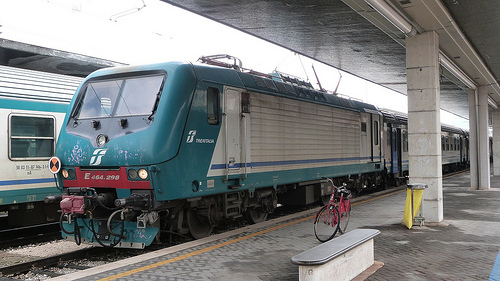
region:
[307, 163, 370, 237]
The bicycle is red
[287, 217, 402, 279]
The bench is in front of the bicycle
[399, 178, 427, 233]
The trash bag is yellow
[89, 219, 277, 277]
The line is yellow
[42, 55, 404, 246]
The train is green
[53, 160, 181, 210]
The sign on the front of the train is red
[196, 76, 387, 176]
The side of the train is white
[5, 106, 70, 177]
The window is closed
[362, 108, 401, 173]
The door of the train is closed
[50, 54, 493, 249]
An aqua and white train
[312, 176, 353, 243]
A red bike parked near train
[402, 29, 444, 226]
A concrete pillar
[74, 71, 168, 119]
A windsheild of a train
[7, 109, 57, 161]
A window on side of train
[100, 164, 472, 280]
A yellow line on ground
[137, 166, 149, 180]
A round headlight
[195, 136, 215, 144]
Words on the side of train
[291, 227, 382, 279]
A bench on platform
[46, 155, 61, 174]
An orange and black sign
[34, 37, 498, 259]
train on the tracks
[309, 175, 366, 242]
red and black bike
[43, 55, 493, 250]
train in the station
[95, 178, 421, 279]
yellow line painted on the ground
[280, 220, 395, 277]
small concrete bench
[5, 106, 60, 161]
window on the side of the train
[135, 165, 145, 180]
light on the front of the train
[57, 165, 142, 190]
red paint on the front of the train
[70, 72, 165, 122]
windows on the front of the train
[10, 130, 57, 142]
metal bar on the window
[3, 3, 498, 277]
scene outside at a train station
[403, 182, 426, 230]
yellow trash receptacle on the platform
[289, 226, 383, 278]
solid cement gray and light tan bench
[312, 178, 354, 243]
red bicycle parked on the platform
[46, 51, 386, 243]
blue and gray train engine with red trim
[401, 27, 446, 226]
light gray cement block support column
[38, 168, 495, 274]
gray cobblestone on the platform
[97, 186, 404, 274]
yellow painted line on the platform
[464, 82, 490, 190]
side by side gray support columns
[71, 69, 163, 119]
front windows of the train engine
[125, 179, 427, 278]
yellow line next to the train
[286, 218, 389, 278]
bench on the platform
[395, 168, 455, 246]
trash bag next to pole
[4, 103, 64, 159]
window on the train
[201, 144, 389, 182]
blue line along the train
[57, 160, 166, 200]
head lights on the train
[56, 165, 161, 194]
red in the front of train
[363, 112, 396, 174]
door on the train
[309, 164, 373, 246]
bike is red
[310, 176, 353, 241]
bicycle sitting near train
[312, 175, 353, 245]
pink bicycle near train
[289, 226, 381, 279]
bench at train station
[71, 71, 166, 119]
front windshield of train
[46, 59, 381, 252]
first car of train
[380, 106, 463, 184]
passenger car of train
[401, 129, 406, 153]
passenger window of train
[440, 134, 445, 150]
passenger window of train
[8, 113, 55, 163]
passenger window of train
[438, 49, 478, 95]
flouroscent lighting in train station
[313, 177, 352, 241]
parked bike with turned front wheel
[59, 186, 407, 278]
yellow line on platform